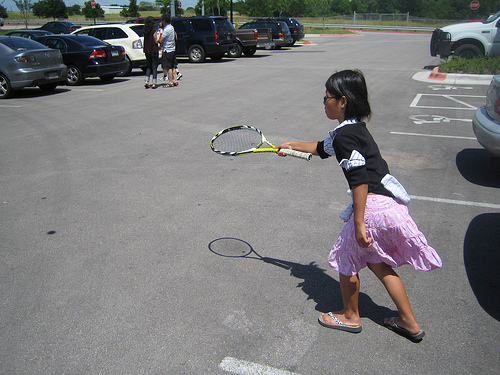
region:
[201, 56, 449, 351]
A young girl is playing with a tennis racket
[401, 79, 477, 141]
Handicapped parking space symbols painted on the pavement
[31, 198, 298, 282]
The tennis racket and ball's shadows against the pavement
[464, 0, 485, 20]
A stop sign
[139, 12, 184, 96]
A group of three people are standing in the parking lot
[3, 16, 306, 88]
Cars parked in the parking lot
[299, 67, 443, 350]
The little girl is wearing a light pink skirt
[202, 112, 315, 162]
The tennis racket is yellow, black and white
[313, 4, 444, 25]
A chain linked fence is across the street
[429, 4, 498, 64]
The front of a large white truck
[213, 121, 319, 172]
A person holds a tennis racket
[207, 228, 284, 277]
A shadow of a tennis racket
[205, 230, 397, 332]
The shadow of a person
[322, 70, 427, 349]
A girl in the parking lot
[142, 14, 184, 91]
Three people stand together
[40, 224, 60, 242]
The shadow of a ball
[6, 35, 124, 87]
Two cars next to each other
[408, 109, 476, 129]
A handicapped sign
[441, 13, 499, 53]
The truck is white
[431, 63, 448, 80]
The curb is red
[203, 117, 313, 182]
A tennis racket in the little girls hand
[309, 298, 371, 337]
The left foot little girl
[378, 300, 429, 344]
The right foot of the little girl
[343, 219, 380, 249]
The hand of the little girl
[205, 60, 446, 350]
The little girl holds a tennis racket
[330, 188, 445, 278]
The little girls skirt is pink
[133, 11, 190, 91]
A family standing in the parking lot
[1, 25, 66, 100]
A grey car is parked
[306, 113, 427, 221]
The little girls shirt is black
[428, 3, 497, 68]
A white pickup truck is parked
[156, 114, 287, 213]
yellow and black tennis racket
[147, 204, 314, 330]
shadow on the cement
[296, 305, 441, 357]
two flip flops on feet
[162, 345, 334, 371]
white line on pavement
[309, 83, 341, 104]
glasses on a child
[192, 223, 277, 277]
shadow of a tennis racket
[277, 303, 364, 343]
black and white sandal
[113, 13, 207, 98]
people standing on cement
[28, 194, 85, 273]
oil spot on cement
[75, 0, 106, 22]
red and white stop sign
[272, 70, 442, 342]
a young girl standing in the parking lot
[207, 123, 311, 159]
a tennis racket in the girl's hand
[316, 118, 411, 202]
a black shirt on the girl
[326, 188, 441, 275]
a pink dress on the girl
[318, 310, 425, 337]
flip flops on the girl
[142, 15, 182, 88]
a group of people standing in the parking lot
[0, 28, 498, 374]
a large, paved parking lot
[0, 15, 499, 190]
cars parked in the parking lot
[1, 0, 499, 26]
trees behind the parking lot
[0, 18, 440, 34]
a metal guard rail behind the parking lot